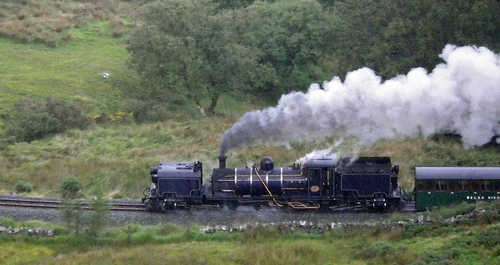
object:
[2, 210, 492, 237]
fence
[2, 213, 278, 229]
gravel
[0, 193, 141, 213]
train tracks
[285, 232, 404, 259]
ground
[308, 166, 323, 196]
door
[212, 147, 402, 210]
engine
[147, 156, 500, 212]
train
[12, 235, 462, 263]
grass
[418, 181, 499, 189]
windows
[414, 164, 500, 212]
train car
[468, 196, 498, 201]
letters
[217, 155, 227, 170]
stack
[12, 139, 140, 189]
pasture fields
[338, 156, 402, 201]
bin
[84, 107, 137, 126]
cluster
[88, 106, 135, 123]
flowers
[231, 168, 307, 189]
banding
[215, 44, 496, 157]
smoke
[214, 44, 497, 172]
steam